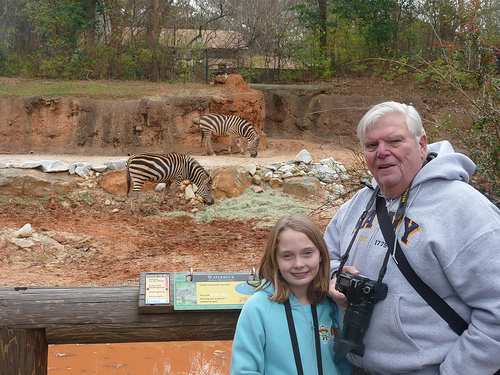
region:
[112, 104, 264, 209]
TWO ZEBRAS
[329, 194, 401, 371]
CAMERA HANGING ON A STRAP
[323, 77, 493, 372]
A MAN WEARING A SWEAT SHIRT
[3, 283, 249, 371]
A WOODEN FENCE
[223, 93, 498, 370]
A MAN AND A YOUNG GIRL STANDING TOGETHER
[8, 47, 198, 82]
TREES IN THE BACKGROUND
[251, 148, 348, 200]
SOME ROCKS IN THE BACKGROUND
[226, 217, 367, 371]
A YOUNG GIRL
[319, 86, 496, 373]
A MAN HOLDING A CAMERA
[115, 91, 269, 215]
TWO ZEBRAS AT THE ZOO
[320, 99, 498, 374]
a man wearing a sweatshirt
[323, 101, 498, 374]
a man holding a camera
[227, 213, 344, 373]
a young girl wearing a blue sweatshirt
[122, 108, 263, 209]
a pair of zebras eating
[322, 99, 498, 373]
a man with gray hair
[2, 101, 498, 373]
two people standing in front of a wooden fence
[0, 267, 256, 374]
a sign on a wooden fence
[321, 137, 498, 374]
a grey sweatshirt with black and yellow lettering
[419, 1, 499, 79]
bushes with red flowers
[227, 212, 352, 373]
a young girl with light brown hair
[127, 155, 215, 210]
zebra eating at a zoo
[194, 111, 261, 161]
zebra eating at a zoo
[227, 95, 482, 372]
girl and her grandfather at zoo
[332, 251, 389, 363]
camera to take pictures of animals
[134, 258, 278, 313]
sign telling what kind of animal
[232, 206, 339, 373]
girl in blue shirt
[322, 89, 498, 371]
older man with camera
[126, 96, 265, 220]
two zebras at a zoo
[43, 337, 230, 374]
muddy water at zoo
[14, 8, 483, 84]
bare trees in background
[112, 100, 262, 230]
Pair of zebras grazing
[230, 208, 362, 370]
Young girl in blue shirt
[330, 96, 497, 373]
Heavyset man holding camera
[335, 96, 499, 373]
Man with white hair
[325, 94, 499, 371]
Man with grey sweatshirt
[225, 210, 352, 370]
Girl with blonde hair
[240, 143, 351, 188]
Pile of white rocks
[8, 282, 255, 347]
Round wooden fence railing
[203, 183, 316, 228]
Hay on the ground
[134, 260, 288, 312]
Sign on fence railing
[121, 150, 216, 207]
zebra grazing on grass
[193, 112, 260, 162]
zebra is black and white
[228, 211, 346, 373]
girl wearing blue sweater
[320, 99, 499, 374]
man holding black camera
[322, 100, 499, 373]
man wearing grey sweatshirt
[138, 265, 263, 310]
informational sign on post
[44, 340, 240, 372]
brown muddy water behind girl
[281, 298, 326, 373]
black strap around girls neck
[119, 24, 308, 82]
brown building in distance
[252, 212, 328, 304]
girl has medium length hair